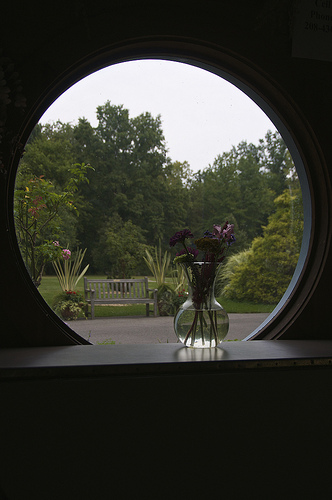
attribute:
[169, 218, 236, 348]
flowers — differently colored, fresh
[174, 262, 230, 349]
vase — flower-filled, half-filled, water-filled, glass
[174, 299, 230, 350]
bottom — bulbous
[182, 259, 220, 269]
opening — narrow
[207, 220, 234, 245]
flower — pink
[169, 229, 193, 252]
flower — purple, in bloom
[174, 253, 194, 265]
flower — green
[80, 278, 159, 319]
bench — wooden, gray, cobbler's bench, place to sit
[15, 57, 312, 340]
window — circular, round, large, atypical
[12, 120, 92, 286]
tree — leaf-filled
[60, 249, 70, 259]
flower — pink, lavender, blooming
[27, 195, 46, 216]
leaves — red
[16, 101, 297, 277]
trees — green, leafy, tall, distant, plentiful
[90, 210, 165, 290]
tree — little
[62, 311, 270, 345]
pavement — gray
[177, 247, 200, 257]
flower — purple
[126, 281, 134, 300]
slat — vertical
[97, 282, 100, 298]
slat — vertical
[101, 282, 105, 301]
slat — vertical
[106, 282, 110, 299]
slat — vertical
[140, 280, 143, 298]
slat — vertical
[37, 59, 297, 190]
sky — hazy, cloudy, gray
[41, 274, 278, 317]
grass — green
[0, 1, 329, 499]
interior — dark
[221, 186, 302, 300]
bush — tall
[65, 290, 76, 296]
flowers — red